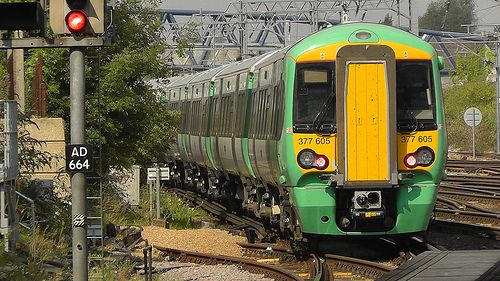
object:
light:
[65, 10, 86, 32]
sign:
[146, 168, 169, 182]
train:
[126, 23, 451, 234]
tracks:
[163, 151, 499, 280]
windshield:
[294, 61, 436, 131]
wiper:
[308, 92, 334, 128]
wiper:
[394, 94, 419, 127]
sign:
[63, 144, 89, 171]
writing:
[67, 146, 89, 171]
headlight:
[315, 154, 325, 167]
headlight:
[407, 156, 416, 167]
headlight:
[298, 150, 314, 167]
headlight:
[419, 146, 434, 165]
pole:
[67, 50, 89, 281]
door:
[348, 63, 390, 182]